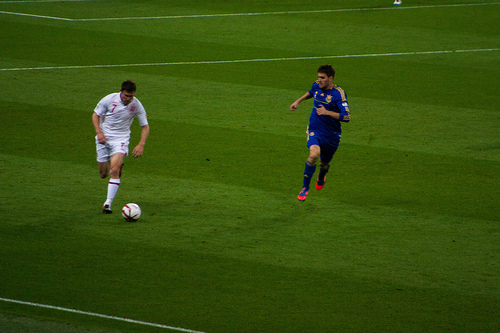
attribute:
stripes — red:
[122, 206, 136, 221]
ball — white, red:
[121, 202, 141, 223]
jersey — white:
[92, 93, 149, 143]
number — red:
[109, 103, 119, 113]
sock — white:
[105, 179, 120, 205]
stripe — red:
[109, 180, 121, 188]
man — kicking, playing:
[91, 79, 150, 212]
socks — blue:
[304, 160, 333, 189]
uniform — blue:
[305, 79, 350, 164]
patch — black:
[204, 157, 211, 163]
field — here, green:
[1, 2, 499, 332]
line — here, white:
[1, 44, 499, 74]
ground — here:
[1, 2, 499, 332]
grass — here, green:
[1, 4, 498, 332]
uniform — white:
[91, 93, 150, 163]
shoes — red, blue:
[296, 176, 327, 201]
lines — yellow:
[0, 2, 499, 73]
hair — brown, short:
[120, 79, 137, 94]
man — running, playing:
[290, 65, 352, 201]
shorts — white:
[95, 132, 131, 163]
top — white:
[92, 92, 150, 141]